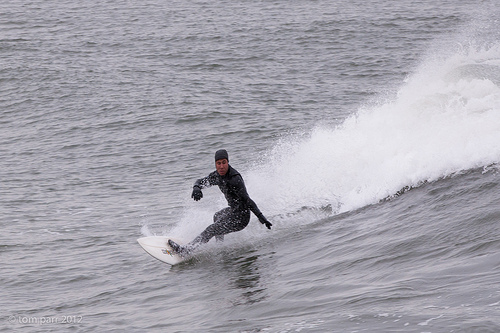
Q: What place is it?
A: It is an ocean.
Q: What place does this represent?
A: It represents the ocean.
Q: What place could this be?
A: It is an ocean.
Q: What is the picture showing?
A: It is showing an ocean.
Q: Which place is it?
A: It is an ocean.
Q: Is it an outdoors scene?
A: Yes, it is outdoors.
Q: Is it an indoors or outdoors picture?
A: It is outdoors.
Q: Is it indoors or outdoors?
A: It is outdoors.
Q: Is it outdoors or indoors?
A: It is outdoors.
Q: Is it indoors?
A: No, it is outdoors.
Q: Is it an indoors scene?
A: No, it is outdoors.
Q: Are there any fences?
A: No, there are no fences.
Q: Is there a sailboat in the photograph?
A: No, there are no sailboats.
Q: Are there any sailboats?
A: No, there are no sailboats.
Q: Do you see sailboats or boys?
A: No, there are no sailboats or boys.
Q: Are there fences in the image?
A: No, there are no fences.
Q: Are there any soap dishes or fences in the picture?
A: No, there are no fences or soap dishes.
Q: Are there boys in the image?
A: No, there are no boys.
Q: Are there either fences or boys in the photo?
A: No, there are no boys or fences.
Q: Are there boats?
A: No, there are no boats.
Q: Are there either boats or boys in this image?
A: No, there are no boats or boys.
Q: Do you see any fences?
A: No, there are no fences.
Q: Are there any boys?
A: No, there are no boys.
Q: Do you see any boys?
A: No, there are no boys.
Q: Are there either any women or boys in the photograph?
A: No, there are no boys or women.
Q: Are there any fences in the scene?
A: No, there are no fences.